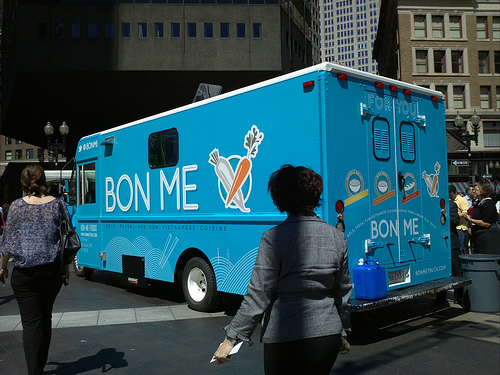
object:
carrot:
[226, 124, 264, 211]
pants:
[10, 258, 65, 373]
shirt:
[221, 212, 351, 344]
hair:
[265, 163, 327, 214]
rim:
[187, 267, 208, 303]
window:
[147, 126, 179, 169]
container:
[353, 256, 388, 300]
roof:
[102, 60, 447, 135]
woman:
[214, 164, 353, 375]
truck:
[57, 60, 473, 330]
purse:
[59, 199, 81, 264]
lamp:
[43, 121, 70, 164]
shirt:
[450, 196, 476, 231]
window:
[189, 23, 196, 37]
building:
[1, 5, 323, 72]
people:
[449, 177, 499, 272]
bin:
[458, 251, 499, 316]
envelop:
[209, 338, 244, 363]